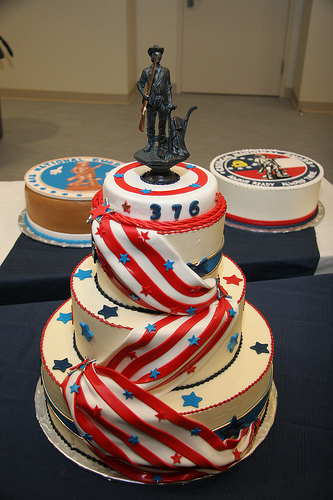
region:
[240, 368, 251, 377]
This is the color cream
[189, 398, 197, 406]
this is light blue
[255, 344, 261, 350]
this is navy blue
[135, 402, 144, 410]
this is the color white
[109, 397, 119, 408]
this is the color red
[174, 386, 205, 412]
this is a light blue star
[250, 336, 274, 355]
this is a dark blue star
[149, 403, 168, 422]
a bright red star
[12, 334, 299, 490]
a bright silver tray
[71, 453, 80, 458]
this is the color silver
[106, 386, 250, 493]
the star is small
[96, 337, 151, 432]
the star is small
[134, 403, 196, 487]
the star is small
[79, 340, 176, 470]
the star is small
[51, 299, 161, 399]
the star is small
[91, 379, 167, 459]
the star is small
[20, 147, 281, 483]
a three tier cake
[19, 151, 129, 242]
a decorated cake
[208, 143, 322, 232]
a decorated cake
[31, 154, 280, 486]
a patriotic decorated cake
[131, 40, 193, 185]
a sculpture of a man and dog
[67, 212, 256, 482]
red and white flag bunting icing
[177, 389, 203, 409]
a blue candy star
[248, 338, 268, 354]
a blue candy star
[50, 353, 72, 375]
a blue candy star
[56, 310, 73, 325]
a blue candy star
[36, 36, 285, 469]
the cake on the table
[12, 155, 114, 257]
the cake on the table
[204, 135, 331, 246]
the cake on the table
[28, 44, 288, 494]
the cake is tiered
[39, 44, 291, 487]
the cake is red white and blue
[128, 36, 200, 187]
the figurine on top of the cake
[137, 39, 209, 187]
the figurine holding a rifle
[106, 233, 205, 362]
the stars on the cak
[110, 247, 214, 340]
the stars are red and blue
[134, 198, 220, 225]
the number 376 on the cake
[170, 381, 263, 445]
the star is purple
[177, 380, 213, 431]
the star is purple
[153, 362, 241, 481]
the star is purple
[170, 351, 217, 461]
the star is purple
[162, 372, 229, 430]
the star is purple